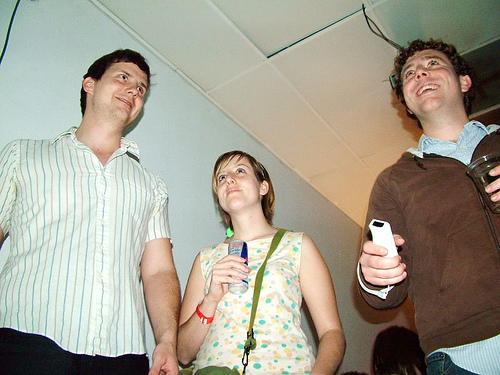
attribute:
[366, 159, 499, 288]
jacket — brown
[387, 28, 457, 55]
hair — curly, brown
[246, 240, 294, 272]
strap — green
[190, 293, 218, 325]
bracelet — red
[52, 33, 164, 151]
man — smiling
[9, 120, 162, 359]
shirt — stripes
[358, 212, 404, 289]
controller — white